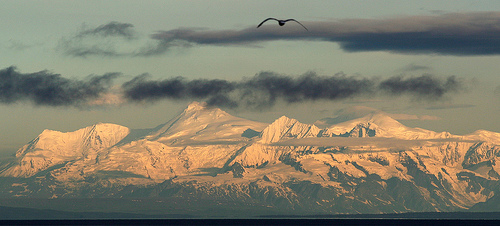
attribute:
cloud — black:
[0, 66, 476, 112]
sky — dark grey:
[4, 0, 499, 149]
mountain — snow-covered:
[151, 97, 263, 143]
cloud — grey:
[155, 9, 497, 55]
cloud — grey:
[0, 69, 463, 104]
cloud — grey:
[70, 19, 136, 57]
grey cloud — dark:
[127, 66, 464, 109]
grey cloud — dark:
[161, 10, 498, 58]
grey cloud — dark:
[3, 62, 123, 111]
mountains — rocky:
[11, 122, 58, 182]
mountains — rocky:
[76, 117, 121, 157]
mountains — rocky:
[108, 130, 176, 175]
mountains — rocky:
[161, 90, 261, 140]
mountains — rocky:
[226, 128, 286, 174]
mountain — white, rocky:
[143, 112, 400, 193]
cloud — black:
[143, 7, 410, 68]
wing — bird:
[288, 12, 313, 34]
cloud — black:
[0, 64, 455, 108]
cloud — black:
[78, 10, 498, 61]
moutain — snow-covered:
[9, 120, 126, 178]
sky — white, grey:
[0, 0, 497, 132]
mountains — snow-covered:
[0, 94, 497, 219]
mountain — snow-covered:
[12, 95, 498, 211]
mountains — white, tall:
[67, 99, 493, 206]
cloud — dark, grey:
[26, 34, 142, 93]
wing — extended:
[257, 15, 281, 31]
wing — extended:
[281, 16, 309, 35]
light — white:
[7, 100, 494, 188]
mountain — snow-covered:
[322, 109, 409, 140]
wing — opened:
[286, 16, 313, 36]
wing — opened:
[251, 13, 272, 33]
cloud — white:
[391, 110, 440, 122]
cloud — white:
[88, 92, 118, 112]